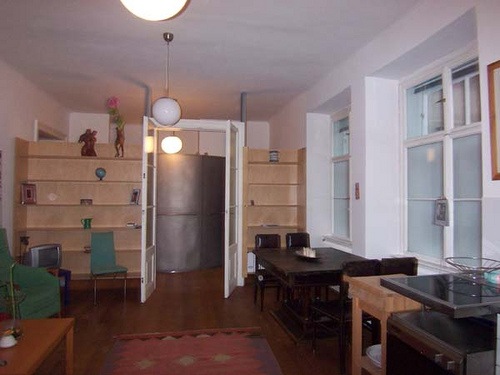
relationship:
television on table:
[23, 231, 75, 271] [329, 259, 406, 364]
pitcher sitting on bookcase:
[79, 216, 96, 230] [12, 118, 159, 306]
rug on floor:
[83, 324, 278, 374] [40, 264, 397, 374]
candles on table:
[292, 235, 334, 268] [315, 230, 377, 272]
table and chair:
[252, 247, 369, 342] [256, 233, 281, 312]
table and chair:
[252, 247, 369, 342] [287, 232, 309, 251]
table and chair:
[252, 247, 369, 342] [312, 259, 380, 364]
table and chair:
[252, 247, 369, 342] [382, 257, 417, 277]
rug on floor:
[96, 326, 280, 375] [24, 260, 384, 373]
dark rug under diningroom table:
[269, 297, 365, 344] [244, 232, 419, 337]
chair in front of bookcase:
[83, 225, 131, 302] [14, 139, 141, 280]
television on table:
[23, 244, 63, 270] [50, 271, 72, 301]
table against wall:
[252, 232, 369, 334] [269, 0, 499, 292]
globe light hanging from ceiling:
[157, 133, 183, 155] [152, 130, 227, 134]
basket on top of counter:
[445, 256, 500, 280] [378, 267, 498, 317]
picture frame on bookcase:
[122, 184, 161, 222] [14, 139, 141, 280]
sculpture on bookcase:
[78, 129, 98, 157] [14, 139, 141, 280]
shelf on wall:
[18, 137, 158, 282] [0, 129, 78, 235]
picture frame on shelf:
[19, 182, 38, 204] [11, 140, 139, 273]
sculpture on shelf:
[77, 119, 104, 171] [64, 146, 141, 163]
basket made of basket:
[445, 256, 500, 280] [445, 256, 500, 280]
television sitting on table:
[23, 244, 63, 270] [51, 269, 72, 306]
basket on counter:
[432, 242, 499, 296] [375, 265, 498, 327]